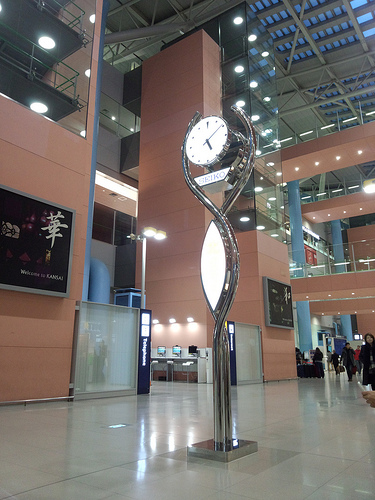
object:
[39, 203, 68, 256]
writing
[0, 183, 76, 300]
wallpicture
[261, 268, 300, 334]
screen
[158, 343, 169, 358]
computers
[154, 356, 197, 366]
table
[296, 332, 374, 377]
group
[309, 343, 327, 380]
people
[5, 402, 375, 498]
floor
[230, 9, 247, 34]
lights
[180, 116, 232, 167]
clock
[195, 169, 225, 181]
seiko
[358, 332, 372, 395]
woman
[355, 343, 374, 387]
black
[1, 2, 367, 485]
mall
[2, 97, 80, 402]
wall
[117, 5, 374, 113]
ceiling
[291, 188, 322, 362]
beam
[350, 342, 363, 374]
person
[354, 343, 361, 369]
red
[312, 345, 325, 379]
prson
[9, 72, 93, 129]
rail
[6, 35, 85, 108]
safetyrail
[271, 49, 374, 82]
girders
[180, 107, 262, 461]
clocktower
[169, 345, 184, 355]
computer monitors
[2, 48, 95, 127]
secondfloor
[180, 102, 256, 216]
oranments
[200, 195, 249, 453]
frame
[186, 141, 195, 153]
cardinal numbers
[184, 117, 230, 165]
5.10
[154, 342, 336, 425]
hallway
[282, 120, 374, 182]
bridge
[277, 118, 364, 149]
rails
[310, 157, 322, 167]
lights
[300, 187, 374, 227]
bridge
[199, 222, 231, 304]
light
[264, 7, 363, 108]
sunlights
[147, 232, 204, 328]
wall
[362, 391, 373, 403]
hand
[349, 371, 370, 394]
phone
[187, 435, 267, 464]
base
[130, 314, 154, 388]
towers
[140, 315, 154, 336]
light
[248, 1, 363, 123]
skylight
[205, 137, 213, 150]
hourhand